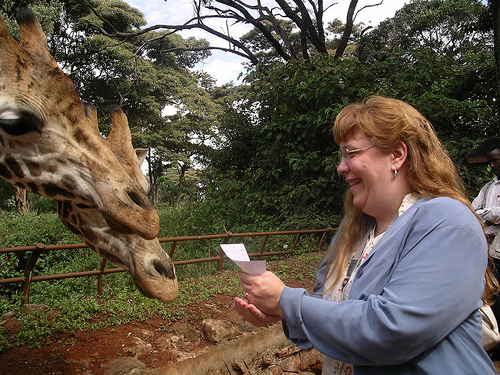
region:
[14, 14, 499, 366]
The woman is feeding the giraffe.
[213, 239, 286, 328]
hand holding paper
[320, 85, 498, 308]
hair is long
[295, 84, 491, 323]
hair is blonde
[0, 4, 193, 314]
giraffe is brown and white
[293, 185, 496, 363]
jacket is blue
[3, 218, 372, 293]
Fence on ground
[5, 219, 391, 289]
fence is brown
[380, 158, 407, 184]
The woman is wearing an earring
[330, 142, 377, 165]
The woman is wearing glasses.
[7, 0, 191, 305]
Two giraffes eating from woman.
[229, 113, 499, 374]
Woman feeding two giraffes.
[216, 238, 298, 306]
Woman holding white piece of paper in hand.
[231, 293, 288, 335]
Woman holding food for giraffes in hand.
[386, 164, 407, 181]
Woman wearing silve hoop earrings.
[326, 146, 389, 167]
Woman wearing eyeglasses over eyes.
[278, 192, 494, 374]
Woman dressed in light blue jacket.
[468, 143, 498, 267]
Man in background standing with arms crossed.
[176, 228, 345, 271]
Metal fence along animal enclosure.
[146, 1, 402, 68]
Bare trunk of trees growing inside animal enclosure.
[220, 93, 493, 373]
a woman holding paper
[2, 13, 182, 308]
the heads of two giraffes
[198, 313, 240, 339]
a rock in dirt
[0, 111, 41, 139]
a giraffe's eye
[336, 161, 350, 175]
a woman's nose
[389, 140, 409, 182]
a woman's ear with an earring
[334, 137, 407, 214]
the side of a woman's face with glasses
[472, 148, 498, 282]
a man standing at a distance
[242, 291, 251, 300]
a ring on a woman's finger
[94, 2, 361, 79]
branches from a tall tree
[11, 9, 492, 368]
a woman in front of giraffes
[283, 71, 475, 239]
woman is smiling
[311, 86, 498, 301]
woman has long hair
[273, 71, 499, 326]
blond woman wears glasses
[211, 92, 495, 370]
woman holds a white paper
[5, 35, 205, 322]
two long heads of giraffes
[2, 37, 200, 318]
heads of giraffes are thin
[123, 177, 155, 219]
nostril of giraffe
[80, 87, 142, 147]
two horns of giraffe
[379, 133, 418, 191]
ear with an earring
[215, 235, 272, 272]
a white piece of a paper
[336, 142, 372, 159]
a woman's eyeglasses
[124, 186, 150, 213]
the nose of a giraffe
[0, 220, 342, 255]
a long brown pole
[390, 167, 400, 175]
a woman's earring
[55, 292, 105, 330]
a small section of grass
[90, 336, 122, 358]
brown dirt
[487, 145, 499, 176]
the head of a man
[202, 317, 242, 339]
a large gray rock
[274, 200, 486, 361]
the arm of a woman